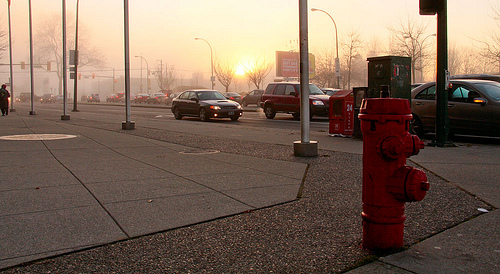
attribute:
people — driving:
[196, 90, 222, 101]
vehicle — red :
[260, 80, 329, 122]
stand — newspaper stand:
[324, 87, 355, 138]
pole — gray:
[45, 0, 77, 107]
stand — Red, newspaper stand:
[327, 88, 357, 137]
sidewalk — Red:
[3, 108, 498, 272]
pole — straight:
[118, 0, 137, 132]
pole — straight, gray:
[291, 0, 322, 157]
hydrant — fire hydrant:
[332, 80, 456, 253]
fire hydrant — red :
[351, 87, 434, 262]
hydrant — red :
[342, 79, 432, 250]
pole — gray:
[19, 3, 42, 108]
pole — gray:
[49, 1, 86, 104]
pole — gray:
[99, 4, 149, 115]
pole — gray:
[262, 5, 339, 132]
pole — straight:
[4, 0, 15, 112]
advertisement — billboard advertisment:
[271, 46, 323, 86]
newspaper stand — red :
[326, 88, 355, 137]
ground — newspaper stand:
[328, 112, 397, 167]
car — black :
[144, 40, 269, 135]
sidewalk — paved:
[3, 109, 307, 269]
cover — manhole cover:
[181, 148, 221, 155]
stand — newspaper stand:
[329, 91, 351, 137]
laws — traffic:
[64, 44, 85, 94]